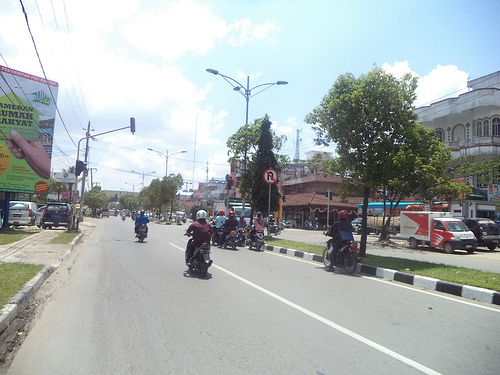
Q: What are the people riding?
A: Motorcycle.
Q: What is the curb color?
A: White.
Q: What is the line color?
A: White.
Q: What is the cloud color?
A: White.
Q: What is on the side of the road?
A: A tree.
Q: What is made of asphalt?
A: The street.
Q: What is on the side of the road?
A: A billboard.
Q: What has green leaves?
A: A tree.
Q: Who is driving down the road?
A: Motorcyclists.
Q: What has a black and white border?
A: The curb.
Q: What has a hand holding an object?
A: A large billboard.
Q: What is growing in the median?
A: Trees.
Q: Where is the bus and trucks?
A: On the road.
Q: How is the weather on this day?
A: Sunny.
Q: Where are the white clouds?
A: In the sky.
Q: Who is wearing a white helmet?
A: A motorcyclist.